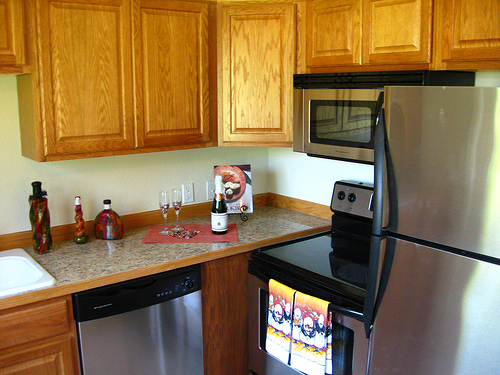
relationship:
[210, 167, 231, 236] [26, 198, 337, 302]
wine on counter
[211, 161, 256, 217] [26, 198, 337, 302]
book on counter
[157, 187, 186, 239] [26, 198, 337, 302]
glasses on counter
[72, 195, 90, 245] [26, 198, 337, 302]
bottles on counter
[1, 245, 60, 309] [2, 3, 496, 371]
sink in kitchen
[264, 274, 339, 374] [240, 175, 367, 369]
towels over oven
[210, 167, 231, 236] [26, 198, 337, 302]
bottle on counter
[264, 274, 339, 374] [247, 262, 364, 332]
towels on handle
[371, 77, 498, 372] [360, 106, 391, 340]
refrigerator has handles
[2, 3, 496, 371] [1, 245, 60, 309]
kitchen has sink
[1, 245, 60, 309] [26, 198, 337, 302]
sink in counter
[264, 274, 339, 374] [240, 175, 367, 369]
towels over stove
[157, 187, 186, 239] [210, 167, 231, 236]
glasses for wine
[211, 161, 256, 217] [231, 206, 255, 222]
book on stand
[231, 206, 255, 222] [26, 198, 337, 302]
stand on counter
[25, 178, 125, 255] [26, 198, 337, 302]
ornaments on countertop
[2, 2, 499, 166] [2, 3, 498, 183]
cabinets on wall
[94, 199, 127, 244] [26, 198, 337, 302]
jar on counter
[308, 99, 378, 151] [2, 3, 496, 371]
window reflecting kitchen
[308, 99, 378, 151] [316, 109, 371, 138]
door reflecting light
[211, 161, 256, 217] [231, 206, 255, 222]
menu on stand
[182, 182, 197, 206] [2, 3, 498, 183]
socket in wall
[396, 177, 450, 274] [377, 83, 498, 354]
smudges on door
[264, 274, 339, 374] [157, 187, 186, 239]
towels for dishes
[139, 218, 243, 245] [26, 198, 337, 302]
placemat on counter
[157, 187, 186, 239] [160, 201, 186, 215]
glasses with candy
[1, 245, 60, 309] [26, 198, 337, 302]
sink near counter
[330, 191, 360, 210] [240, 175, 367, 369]
knobs on stove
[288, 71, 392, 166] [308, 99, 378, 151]
microwave has window